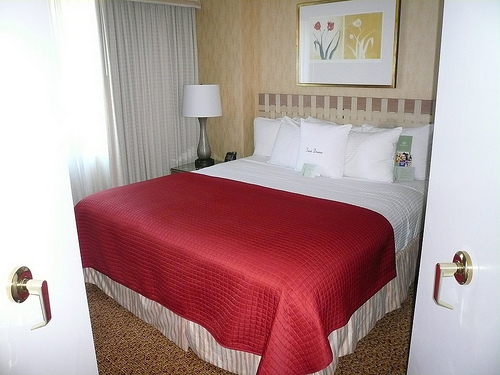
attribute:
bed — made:
[81, 132, 417, 365]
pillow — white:
[292, 115, 352, 182]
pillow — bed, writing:
[306, 117, 357, 181]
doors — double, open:
[411, 5, 497, 372]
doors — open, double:
[0, 2, 98, 373]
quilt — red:
[86, 174, 433, 373]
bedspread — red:
[70, 169, 401, 361]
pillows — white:
[249, 113, 427, 186]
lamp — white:
[183, 79, 223, 156]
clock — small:
[222, 151, 235, 163]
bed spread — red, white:
[74, 171, 398, 374]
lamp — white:
[181, 83, 221, 170]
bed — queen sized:
[68, 112, 435, 368]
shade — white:
[181, 82, 221, 118]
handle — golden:
[12, 266, 51, 332]